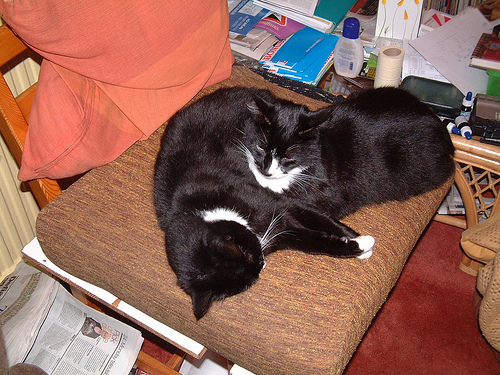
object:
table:
[230, 0, 498, 275]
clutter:
[231, 0, 498, 110]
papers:
[244, 0, 356, 37]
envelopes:
[260, 24, 340, 83]